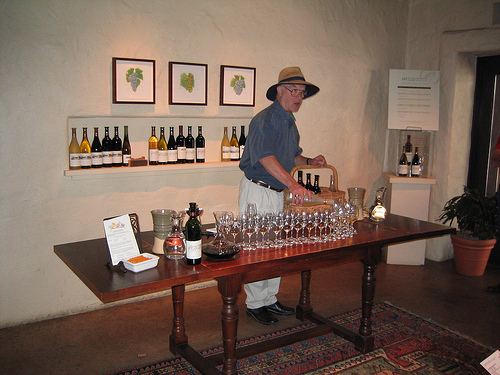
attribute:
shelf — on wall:
[65, 160, 242, 177]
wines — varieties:
[184, 198, 200, 263]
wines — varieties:
[219, 121, 229, 160]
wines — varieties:
[179, 121, 198, 162]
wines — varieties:
[167, 123, 182, 163]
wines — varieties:
[157, 120, 176, 170]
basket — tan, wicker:
[287, 162, 340, 217]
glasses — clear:
[214, 186, 374, 247]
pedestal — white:
[385, 172, 437, 266]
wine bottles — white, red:
[66, 123, 246, 170]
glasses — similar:
[209, 196, 364, 249]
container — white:
[121, 252, 158, 274]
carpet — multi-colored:
[136, 290, 499, 373]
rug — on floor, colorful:
[123, 297, 494, 373]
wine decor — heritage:
[112, 56, 157, 106]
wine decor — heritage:
[166, 54, 211, 106]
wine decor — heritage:
[216, 57, 259, 106]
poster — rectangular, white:
[382, 65, 440, 129]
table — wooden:
[57, 166, 499, 293]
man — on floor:
[190, 64, 442, 300]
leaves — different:
[119, 50, 306, 102]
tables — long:
[58, 130, 420, 373]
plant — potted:
[421, 177, 498, 272]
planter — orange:
[440, 219, 495, 279]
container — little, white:
[126, 263, 154, 273]